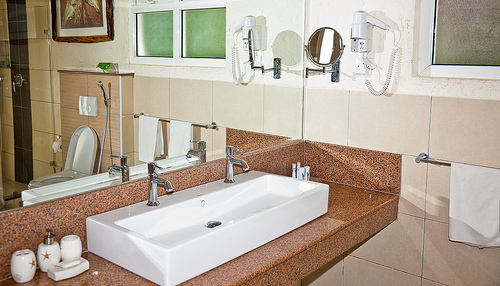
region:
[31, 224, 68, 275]
soap dispenser with gold star on it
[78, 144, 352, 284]
white sink with double faucets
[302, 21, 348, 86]
small round mirror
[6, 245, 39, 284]
white toothbrush holder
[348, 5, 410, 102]
hair dryer attached to wall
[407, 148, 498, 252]
white towel hanging on towel rack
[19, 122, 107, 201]
toilet with open lid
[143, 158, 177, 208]
chrome looking sink faucet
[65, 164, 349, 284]
white rectangle sink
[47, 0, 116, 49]
picture with a wood frame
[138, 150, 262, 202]
two silver sink faucets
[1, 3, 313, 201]
mirror above white sick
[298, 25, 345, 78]
small mirror on swivel attached to wall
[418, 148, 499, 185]
silver towel rack on wall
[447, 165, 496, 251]
white towel on towel rack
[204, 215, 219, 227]
silver drain of white sink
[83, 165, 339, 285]
white sink on countertop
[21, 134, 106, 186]
white toilet reflected in mirror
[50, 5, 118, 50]
black framed picture reflected in window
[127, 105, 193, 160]
white towels reflected in mirror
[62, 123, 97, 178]
toilet lid reflected in the mirror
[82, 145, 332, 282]
raised white sink on brown counter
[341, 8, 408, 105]
wall mounted white hair dryer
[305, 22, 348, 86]
wall mounted round mirror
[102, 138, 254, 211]
silver faucets mounted on raised sink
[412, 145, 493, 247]
wall mounted towel rack with white towel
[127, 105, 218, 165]
reflection of towel rack with two white towels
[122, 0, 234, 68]
windows with white frame in mirror reflection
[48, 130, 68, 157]
toilet paper roll mounted on wall in reflection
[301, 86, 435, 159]
large tan tiles on bathroom wall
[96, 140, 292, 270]
white rectangular sink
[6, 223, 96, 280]
white bathroom set on a sink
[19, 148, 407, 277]
reddish brown counter top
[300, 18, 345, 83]
round mirror attached to the wall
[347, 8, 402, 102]
small hair dryer on the wall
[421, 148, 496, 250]
white towel hanging from a rung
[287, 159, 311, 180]
set of bathroom amenities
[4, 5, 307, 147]
reflection of the bathroom in a mirror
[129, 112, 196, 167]
reflection of a pair of towels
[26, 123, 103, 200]
reflection of a toilet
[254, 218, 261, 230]
edge of a table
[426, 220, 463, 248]
part of a wall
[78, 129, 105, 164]
part of a mirror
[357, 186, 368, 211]
edge of a sink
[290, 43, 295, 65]
part of a mirror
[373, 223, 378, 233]
bottom of a sink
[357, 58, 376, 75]
part of a drier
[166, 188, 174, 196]
edge of a tap